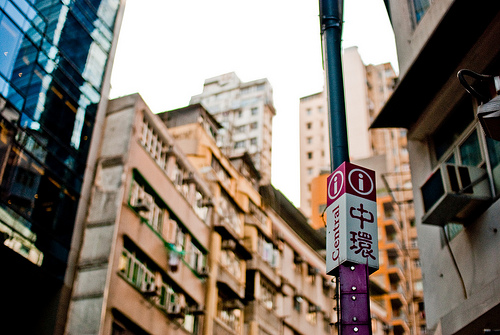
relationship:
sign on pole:
[327, 161, 378, 270] [318, 3, 379, 335]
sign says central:
[327, 161, 378, 270] [328, 206, 344, 264]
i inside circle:
[356, 173, 367, 189] [348, 166, 374, 196]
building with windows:
[2, 3, 125, 333] [8, 15, 77, 127]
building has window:
[2, 3, 125, 333] [131, 263, 143, 283]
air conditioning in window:
[422, 165, 496, 225] [422, 111, 492, 218]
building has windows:
[2, 3, 125, 333] [8, 15, 77, 127]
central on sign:
[328, 206, 344, 264] [327, 161, 378, 270]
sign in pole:
[327, 161, 378, 270] [318, 3, 379, 335]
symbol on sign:
[327, 172, 346, 197] [327, 161, 378, 270]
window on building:
[131, 263, 143, 283] [2, 3, 125, 333]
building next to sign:
[2, 3, 125, 333] [327, 161, 378, 270]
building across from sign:
[2, 3, 125, 333] [327, 161, 378, 270]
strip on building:
[124, 184, 216, 285] [2, 3, 125, 333]